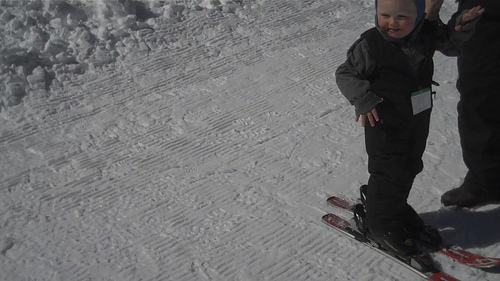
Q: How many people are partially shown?
A: Two.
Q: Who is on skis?
A: The kid.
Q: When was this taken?
A: During the day.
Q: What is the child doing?
A: Standing on skis.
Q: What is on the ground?
A: Snow.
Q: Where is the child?
A: Near a parent.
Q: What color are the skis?
A: Red.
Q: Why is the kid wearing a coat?
A: It's cold.